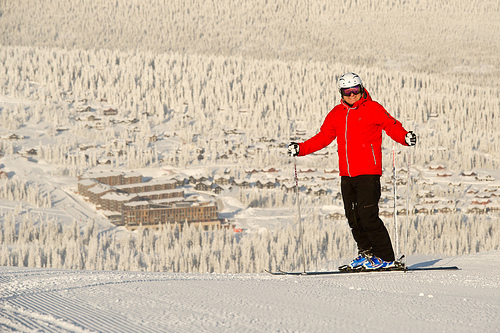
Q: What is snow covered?
A: Buildings.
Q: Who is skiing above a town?
A: A man.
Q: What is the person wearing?
A: A ski jacket.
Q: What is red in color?
A: Ski jacket.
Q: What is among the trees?
A: A ski lodge.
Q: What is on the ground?
A: Snow.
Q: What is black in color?
A: Pants.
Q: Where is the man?
A: On the snow.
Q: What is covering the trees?
A: Snow.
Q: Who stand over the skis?
A: A man.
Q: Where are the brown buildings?
A: Below the hill.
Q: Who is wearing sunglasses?
A: A man.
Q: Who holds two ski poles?
A: The skier.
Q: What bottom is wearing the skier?
A: Black pants.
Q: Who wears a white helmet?
A: A skier.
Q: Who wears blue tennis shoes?
A: A man.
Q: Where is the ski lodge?
A: At the bottom of the mountain.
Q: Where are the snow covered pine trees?
A: Surrounding the ski lodge.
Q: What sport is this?
A: Skiing.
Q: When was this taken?
A: Winter.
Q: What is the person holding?
A: Ski poles.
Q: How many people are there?
A: 1.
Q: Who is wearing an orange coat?
A: Man.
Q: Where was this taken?
A: Mountain.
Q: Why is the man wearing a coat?
A: Cold.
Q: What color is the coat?
A: Orange.